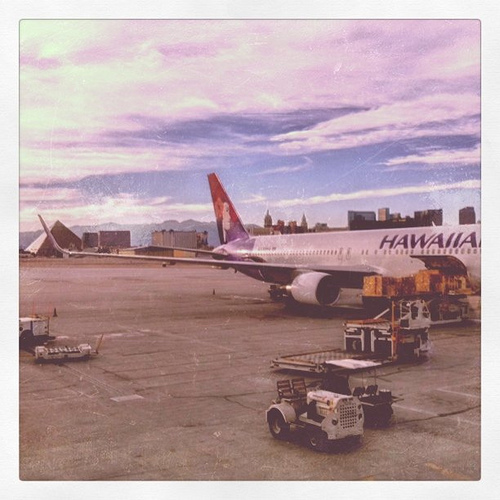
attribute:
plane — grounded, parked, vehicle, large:
[37, 173, 481, 307]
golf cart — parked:
[323, 358, 403, 428]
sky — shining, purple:
[19, 19, 482, 229]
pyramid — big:
[26, 220, 85, 256]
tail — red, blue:
[206, 170, 249, 242]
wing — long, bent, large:
[37, 214, 379, 276]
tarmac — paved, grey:
[20, 254, 480, 482]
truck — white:
[266, 380, 366, 450]